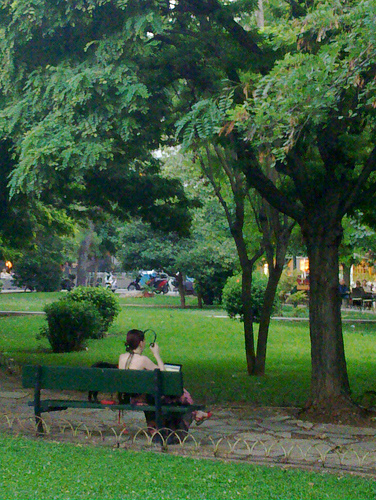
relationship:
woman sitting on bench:
[124, 318, 197, 417] [19, 365, 220, 412]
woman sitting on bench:
[117, 327, 211, 426] [19, 365, 220, 412]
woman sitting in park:
[123, 308, 198, 442] [2, 283, 375, 499]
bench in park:
[20, 353, 195, 452] [2, 283, 375, 499]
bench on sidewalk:
[13, 359, 211, 444] [1, 376, 374, 478]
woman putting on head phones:
[116, 328, 213, 445] [141, 326, 157, 347]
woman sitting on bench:
[115, 311, 177, 396] [19, 365, 220, 412]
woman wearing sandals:
[116, 328, 213, 445] [190, 409, 213, 425]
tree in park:
[289, 0, 375, 429] [2, 283, 375, 499]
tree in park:
[162, 40, 310, 381] [2, 283, 375, 499]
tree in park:
[98, 150, 232, 304] [2, 283, 375, 499]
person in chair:
[355, 279, 364, 292] [363, 298, 373, 308]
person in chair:
[360, 278, 372, 291] [350, 287, 362, 306]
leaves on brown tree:
[0, 0, 373, 231] [0, 0, 376, 421]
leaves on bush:
[214, 61, 314, 142] [218, 267, 285, 321]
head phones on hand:
[141, 326, 157, 347] [148, 341, 160, 353]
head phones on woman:
[141, 326, 157, 347] [114, 324, 219, 436]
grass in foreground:
[6, 441, 373, 495] [2, 332, 347, 496]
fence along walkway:
[6, 408, 374, 471] [2, 381, 371, 481]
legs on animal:
[72, 388, 110, 414] [82, 356, 138, 407]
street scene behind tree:
[1, 256, 364, 317] [210, 0, 375, 429]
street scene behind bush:
[1, 256, 364, 317] [36, 298, 101, 353]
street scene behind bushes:
[1, 256, 364, 317] [62, 284, 122, 337]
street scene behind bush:
[1, 256, 364, 317] [218, 265, 282, 323]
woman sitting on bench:
[116, 328, 213, 445] [19, 365, 220, 412]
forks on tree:
[236, 252, 285, 375] [184, 63, 307, 377]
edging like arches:
[2, 412, 374, 465] [0, 412, 373, 465]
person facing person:
[336, 278, 346, 297] [352, 276, 364, 293]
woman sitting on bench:
[114, 324, 219, 436] [19, 365, 220, 412]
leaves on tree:
[217, 82, 237, 113] [163, 2, 374, 412]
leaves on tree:
[34, 202, 78, 238] [0, 54, 200, 248]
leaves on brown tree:
[0, 1, 165, 202] [0, 0, 376, 430]